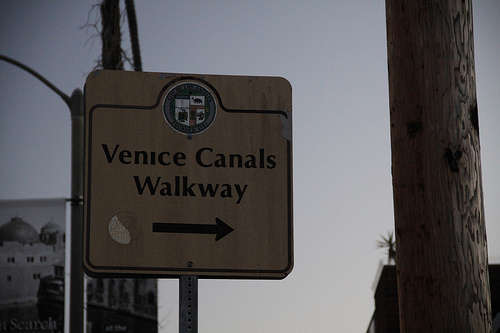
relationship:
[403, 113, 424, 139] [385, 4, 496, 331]
spot on utility pole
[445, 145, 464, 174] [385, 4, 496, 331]
spot on utility pole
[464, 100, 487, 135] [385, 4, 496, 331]
spot on utility pole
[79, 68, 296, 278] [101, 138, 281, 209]
sign says venice canal walkway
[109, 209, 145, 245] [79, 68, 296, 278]
yin yang on sign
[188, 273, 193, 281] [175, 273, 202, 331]
hole in pole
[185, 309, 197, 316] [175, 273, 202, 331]
hole in pole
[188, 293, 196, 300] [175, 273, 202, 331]
hole in pole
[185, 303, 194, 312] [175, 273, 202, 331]
hole in pole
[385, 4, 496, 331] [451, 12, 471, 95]
utility pole has pattern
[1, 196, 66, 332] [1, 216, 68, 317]
banner has picture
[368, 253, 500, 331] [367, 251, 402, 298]
building has corner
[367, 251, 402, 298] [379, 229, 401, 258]
corner has plant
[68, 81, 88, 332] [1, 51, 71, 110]
post has extension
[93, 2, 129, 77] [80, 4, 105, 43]
tree has twig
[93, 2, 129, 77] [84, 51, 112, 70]
tree has twig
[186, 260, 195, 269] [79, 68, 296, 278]
bolt holds sign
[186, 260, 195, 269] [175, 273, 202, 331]
bolt holds pole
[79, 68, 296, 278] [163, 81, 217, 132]
sign has seal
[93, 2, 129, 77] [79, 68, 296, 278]
tree next to sign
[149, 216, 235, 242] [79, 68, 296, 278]
arrow on sign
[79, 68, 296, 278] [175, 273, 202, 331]
sign on pole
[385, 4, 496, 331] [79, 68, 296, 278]
utility pole next to sign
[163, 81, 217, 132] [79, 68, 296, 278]
seal on sign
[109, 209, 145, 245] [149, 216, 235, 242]
yin yang next to arrow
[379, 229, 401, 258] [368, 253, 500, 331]
plant on building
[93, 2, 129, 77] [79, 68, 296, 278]
tree behind sign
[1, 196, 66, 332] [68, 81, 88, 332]
banner on post